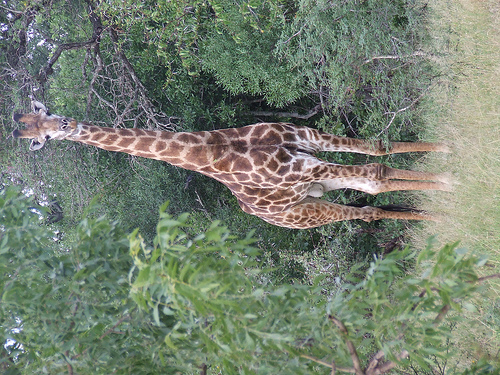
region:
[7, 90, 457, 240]
Giraffe standing on the ground.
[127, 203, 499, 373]
Bush beside the giraffe.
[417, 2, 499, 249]
Brown grass on the ground.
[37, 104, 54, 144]
black eyes on the grass.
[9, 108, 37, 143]
Horns on the giraffe.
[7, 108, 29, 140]
Black tips on the horns.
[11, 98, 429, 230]
brown spots on the giraffe.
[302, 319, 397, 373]
Brown branches on the bush.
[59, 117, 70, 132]
Black nostrils on the giraffe.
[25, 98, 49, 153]
black inside the ears of the giraffe.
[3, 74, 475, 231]
a giraffe standing in a field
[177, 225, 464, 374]
a tree in front of the giraffe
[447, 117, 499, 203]
long green grass of the field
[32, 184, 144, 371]
tress growing behind the giraffe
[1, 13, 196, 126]
dead leafless branches of a tree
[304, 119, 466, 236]
long legs of a giraffe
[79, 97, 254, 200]
long neck of the giraffe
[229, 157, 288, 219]
brown spots of the giraffe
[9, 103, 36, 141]
black and brown horns of the giraffe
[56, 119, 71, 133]
black nose of the giraffe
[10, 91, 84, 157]
a giraffe head.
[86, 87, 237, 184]
a long neck of a giraffe.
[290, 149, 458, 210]
a long giraffe leg.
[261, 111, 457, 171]
a long spotted giraffe leg.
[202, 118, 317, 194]
the chest of a giraffe.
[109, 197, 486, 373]
a large leaf filled bush.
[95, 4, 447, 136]
a tall leaf filled tree.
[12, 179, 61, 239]
a section of sky.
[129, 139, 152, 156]
a brown spot on a giraffe.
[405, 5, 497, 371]
a field of brown grass.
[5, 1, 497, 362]
picture taken outdoors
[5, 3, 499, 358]
picture taken outside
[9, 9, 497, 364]
picture taken during the day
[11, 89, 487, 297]
a single giraffe standing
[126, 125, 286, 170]
the giraffe has brown spots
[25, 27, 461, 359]
the giraffe is standing amongst plants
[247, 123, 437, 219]
the giraffe has long legs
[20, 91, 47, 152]
the giraffe has two ears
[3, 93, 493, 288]
the giraffe is standing still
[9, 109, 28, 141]
the giraffe has two antenna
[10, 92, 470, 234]
Giraffe standing in field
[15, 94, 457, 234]
Giraffe facing photographer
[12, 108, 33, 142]
Ossicones on giraffe's head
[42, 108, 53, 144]
Black eyes of giraffe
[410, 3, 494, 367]
Small grass covered clearing in forest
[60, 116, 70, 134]
Nostrils on giraffe's nose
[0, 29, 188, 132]
Dead tree branches in forest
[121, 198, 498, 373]
Leaf covered shrub in field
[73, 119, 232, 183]
Extended neck of giraffe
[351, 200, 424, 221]
Black tail hairs of giraffe